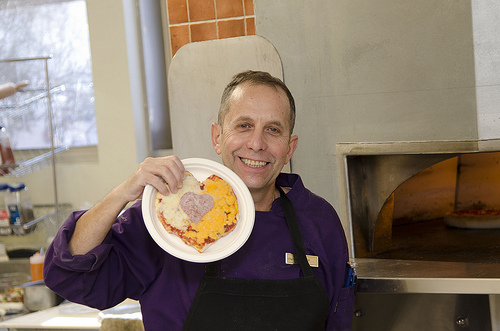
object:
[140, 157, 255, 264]
plate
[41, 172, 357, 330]
coat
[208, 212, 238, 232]
cheese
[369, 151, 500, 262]
painting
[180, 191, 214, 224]
meat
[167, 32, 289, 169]
board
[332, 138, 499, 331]
oven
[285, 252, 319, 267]
name tag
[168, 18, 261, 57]
tiles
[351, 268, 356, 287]
pens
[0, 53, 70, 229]
rack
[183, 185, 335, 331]
apron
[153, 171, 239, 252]
pizza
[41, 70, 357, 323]
man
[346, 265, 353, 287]
pen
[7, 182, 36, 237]
spices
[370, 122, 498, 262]
picture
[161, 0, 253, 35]
brick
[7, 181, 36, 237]
container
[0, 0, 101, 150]
window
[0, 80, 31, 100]
pin